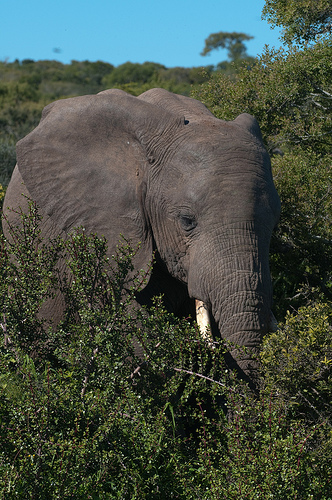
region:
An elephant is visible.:
[60, 119, 189, 290]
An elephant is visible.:
[64, 128, 243, 367]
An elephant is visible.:
[117, 100, 322, 405]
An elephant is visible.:
[14, 220, 310, 380]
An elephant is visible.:
[139, 213, 288, 420]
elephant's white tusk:
[193, 289, 220, 353]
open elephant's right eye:
[175, 206, 201, 236]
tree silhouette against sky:
[194, 20, 262, 69]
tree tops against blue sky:
[7, 32, 201, 84]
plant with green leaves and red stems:
[61, 224, 109, 313]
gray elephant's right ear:
[15, 85, 180, 296]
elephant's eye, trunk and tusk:
[176, 197, 278, 387]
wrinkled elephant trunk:
[206, 223, 268, 377]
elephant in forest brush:
[130, 83, 295, 427]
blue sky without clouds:
[79, 12, 197, 76]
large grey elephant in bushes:
[6, 69, 301, 394]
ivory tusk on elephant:
[186, 297, 222, 355]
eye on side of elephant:
[173, 206, 201, 248]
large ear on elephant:
[20, 103, 161, 293]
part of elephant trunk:
[215, 291, 274, 388]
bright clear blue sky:
[53, 0, 191, 56]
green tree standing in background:
[195, 24, 243, 61]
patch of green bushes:
[10, 445, 89, 495]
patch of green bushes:
[259, 441, 323, 495]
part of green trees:
[271, 64, 325, 141]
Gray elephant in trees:
[6, 78, 303, 384]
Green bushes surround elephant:
[2, 54, 330, 498]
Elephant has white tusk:
[188, 293, 220, 357]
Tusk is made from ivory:
[189, 296, 221, 356]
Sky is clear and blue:
[0, 1, 327, 68]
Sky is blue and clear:
[2, 3, 289, 69]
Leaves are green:
[2, 299, 331, 499]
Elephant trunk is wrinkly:
[194, 197, 293, 397]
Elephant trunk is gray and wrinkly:
[187, 236, 281, 390]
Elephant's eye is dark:
[173, 208, 201, 235]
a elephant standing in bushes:
[0, 110, 297, 328]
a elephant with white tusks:
[182, 142, 311, 357]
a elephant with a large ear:
[20, 93, 263, 342]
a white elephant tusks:
[185, 273, 240, 371]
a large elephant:
[5, 94, 285, 364]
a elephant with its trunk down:
[147, 171, 285, 410]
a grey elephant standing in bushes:
[0, 123, 283, 349]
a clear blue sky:
[23, 4, 223, 74]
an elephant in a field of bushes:
[10, 62, 302, 320]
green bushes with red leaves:
[3, 212, 134, 348]